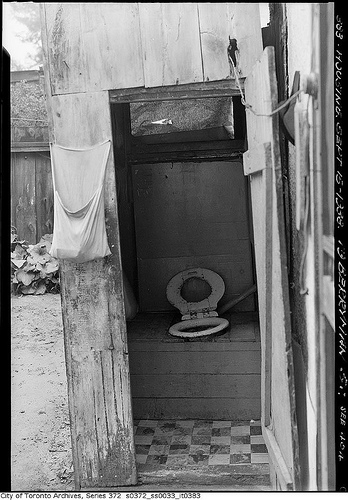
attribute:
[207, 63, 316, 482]
wooden door — outhouse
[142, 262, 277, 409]
base — wooden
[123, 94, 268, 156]
label — film strip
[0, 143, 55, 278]
fence — wooden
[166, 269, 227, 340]
seat — chippped, dirty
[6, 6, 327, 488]
photo — black, white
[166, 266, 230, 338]
commode — old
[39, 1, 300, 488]
outhouse — wooden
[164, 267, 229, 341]
toilet seat — dirty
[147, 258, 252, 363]
toilet — white, dirty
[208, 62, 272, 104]
ground — bare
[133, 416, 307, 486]
floor — dirty, checkered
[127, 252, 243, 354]
toilet seat — beat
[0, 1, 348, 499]
photo — black and white, old